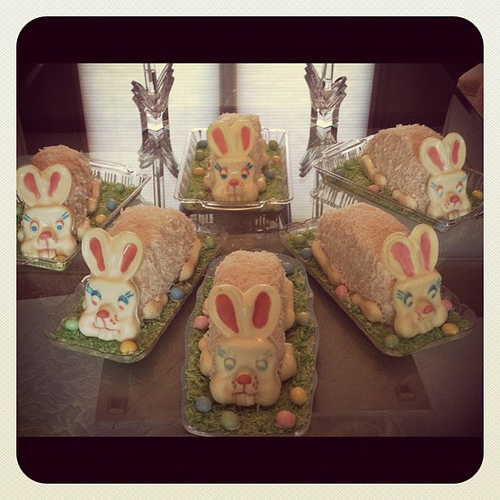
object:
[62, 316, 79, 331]
green egg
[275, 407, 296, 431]
eggs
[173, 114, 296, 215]
container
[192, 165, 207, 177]
eggs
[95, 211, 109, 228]
eggs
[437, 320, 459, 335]
eggs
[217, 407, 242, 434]
eggs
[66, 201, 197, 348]
cake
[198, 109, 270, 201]
cake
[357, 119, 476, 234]
cake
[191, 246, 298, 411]
cake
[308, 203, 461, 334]
cake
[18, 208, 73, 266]
platic face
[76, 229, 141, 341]
platic face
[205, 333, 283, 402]
platic face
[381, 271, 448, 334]
platic face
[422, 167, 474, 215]
platic face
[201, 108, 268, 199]
rabbit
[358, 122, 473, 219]
rabbit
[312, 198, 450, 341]
rabbit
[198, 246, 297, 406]
rabbit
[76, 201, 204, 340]
rabbit